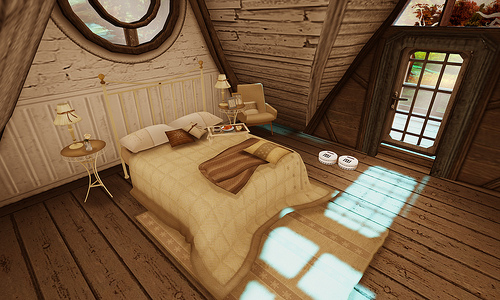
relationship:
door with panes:
[387, 44, 459, 171] [401, 46, 455, 155]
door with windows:
[360, 30, 491, 177] [373, 48, 459, 161]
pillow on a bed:
[121, 115, 179, 151] [141, 107, 304, 248]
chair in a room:
[228, 77, 292, 134] [45, 20, 385, 291]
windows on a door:
[385, 44, 460, 159] [360, 30, 491, 177]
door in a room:
[360, 30, 491, 177] [4, 88, 499, 298]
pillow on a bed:
[242, 138, 296, 165] [115, 115, 310, 257]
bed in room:
[95, 60, 332, 279] [4, 2, 499, 294]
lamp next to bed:
[52, 101, 85, 150] [119, 109, 311, 250]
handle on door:
[387, 82, 408, 113] [372, 43, 466, 168]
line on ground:
[4, 207, 49, 299] [1, 120, 499, 298]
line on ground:
[34, 196, 103, 298] [1, 120, 499, 298]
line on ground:
[64, 185, 154, 298] [1, 120, 499, 298]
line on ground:
[91, 173, 218, 298] [1, 120, 499, 298]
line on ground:
[109, 166, 136, 189] [1, 120, 499, 298]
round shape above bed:
[51, 0, 188, 64] [98, 74, 308, 249]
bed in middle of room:
[117, 109, 311, 250] [89, 101, 391, 293]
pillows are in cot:
[120, 108, 228, 155] [118, 107, 358, 289]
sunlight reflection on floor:
[241, 152, 431, 297] [252, 166, 437, 297]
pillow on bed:
[164, 128, 197, 148] [130, 101, 335, 251]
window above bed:
[71, 0, 180, 73] [102, 92, 339, 294]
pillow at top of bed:
[187, 123, 204, 138] [118, 106, 322, 290]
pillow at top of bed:
[158, 126, 200, 147] [118, 106, 322, 290]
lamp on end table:
[52, 97, 90, 151] [42, 73, 136, 263]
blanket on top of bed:
[202, 137, 283, 197] [117, 118, 324, 270]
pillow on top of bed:
[245, 135, 291, 170] [117, 118, 324, 270]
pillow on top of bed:
[164, 128, 197, 148] [117, 118, 324, 270]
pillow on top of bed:
[181, 120, 208, 139] [117, 118, 324, 270]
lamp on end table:
[52, 101, 85, 150] [59, 137, 116, 203]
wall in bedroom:
[203, 0, 390, 126] [2, 2, 498, 298]